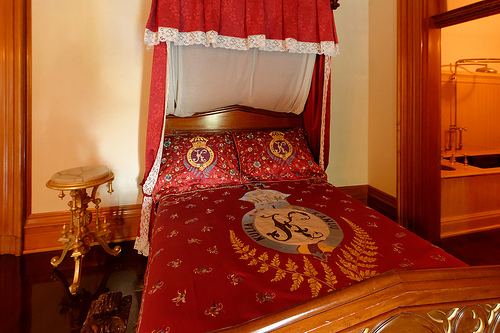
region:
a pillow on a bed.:
[149, 126, 246, 201]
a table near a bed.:
[37, 156, 129, 308]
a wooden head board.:
[159, 97, 321, 159]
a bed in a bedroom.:
[139, 194, 499, 330]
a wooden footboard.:
[249, 260, 494, 330]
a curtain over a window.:
[126, 0, 345, 277]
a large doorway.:
[430, 19, 498, 246]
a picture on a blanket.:
[219, 179, 378, 294]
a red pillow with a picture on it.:
[234, 129, 322, 191]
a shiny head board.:
[160, 88, 326, 160]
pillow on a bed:
[235, 125, 319, 185]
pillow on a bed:
[147, 128, 242, 198]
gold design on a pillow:
[265, 128, 295, 161]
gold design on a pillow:
[187, 132, 217, 174]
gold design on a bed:
[230, 179, 354, 259]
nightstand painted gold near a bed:
[39, 155, 129, 297]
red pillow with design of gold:
[227, 120, 322, 185]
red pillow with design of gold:
[149, 127, 248, 204]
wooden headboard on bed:
[160, 103, 309, 138]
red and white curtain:
[136, 0, 350, 61]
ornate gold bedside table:
[48, 164, 124, 289]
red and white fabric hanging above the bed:
[148, 0, 331, 157]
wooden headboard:
[168, 115, 295, 127]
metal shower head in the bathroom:
[476, 63, 496, 73]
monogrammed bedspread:
[261, 208, 318, 248]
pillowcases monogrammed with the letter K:
[178, 133, 291, 168]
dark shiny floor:
[4, 258, 51, 323]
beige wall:
[43, 7, 133, 161]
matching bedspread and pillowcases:
[171, 135, 308, 295]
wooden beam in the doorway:
[428, 8, 497, 23]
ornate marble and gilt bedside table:
[47, 165, 122, 293]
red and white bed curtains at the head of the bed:
[136, 2, 338, 254]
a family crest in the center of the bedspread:
[228, 180, 378, 297]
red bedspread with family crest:
[135, 181, 475, 331]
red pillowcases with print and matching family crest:
[147, 128, 325, 202]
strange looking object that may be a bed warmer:
[77, 290, 132, 331]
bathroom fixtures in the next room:
[443, 54, 499, 236]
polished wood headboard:
[166, 104, 306, 134]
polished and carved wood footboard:
[215, 265, 497, 331]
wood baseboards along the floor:
[20, 204, 155, 255]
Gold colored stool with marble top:
[32, 123, 120, 317]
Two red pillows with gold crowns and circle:
[113, 118, 352, 198]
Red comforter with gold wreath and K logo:
[123, 175, 491, 330]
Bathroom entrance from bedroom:
[314, 0, 491, 221]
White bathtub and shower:
[435, 43, 498, 268]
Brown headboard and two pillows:
[149, 69, 304, 190]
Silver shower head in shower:
[446, 15, 498, 187]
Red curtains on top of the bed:
[129, 0, 397, 175]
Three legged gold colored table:
[32, 109, 128, 306]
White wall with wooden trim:
[4, 8, 147, 163]